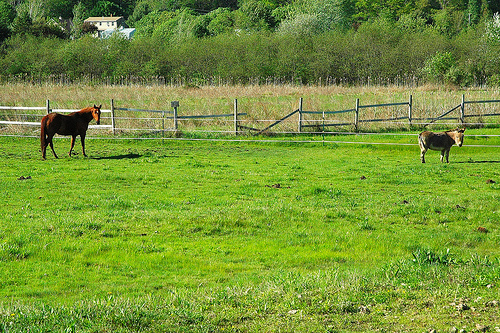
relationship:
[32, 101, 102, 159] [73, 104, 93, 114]
horse has mane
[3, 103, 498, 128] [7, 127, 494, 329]
fence by field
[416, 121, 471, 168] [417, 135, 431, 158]
donkey has tail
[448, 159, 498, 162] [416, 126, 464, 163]
shadow on donkey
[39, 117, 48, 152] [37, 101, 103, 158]
tail of horse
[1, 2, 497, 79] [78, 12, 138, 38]
trees around house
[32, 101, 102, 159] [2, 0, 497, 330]
horse in a field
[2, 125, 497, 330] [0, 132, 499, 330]
grass in green pasture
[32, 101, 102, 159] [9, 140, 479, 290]
horse in grass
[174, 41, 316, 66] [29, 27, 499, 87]
leaves on tree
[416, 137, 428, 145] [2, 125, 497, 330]
part of grass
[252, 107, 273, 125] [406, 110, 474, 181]
part of horse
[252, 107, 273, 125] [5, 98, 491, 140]
part of fence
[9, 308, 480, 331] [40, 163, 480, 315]
edge of lawn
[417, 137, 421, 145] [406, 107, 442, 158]
part of tail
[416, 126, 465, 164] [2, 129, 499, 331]
donkey in pasture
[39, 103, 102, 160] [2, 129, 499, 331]
horse in pasture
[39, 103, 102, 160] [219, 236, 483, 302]
horse in grass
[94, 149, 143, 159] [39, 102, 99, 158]
shadow of horse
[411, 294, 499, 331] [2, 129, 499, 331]
rocks in pasture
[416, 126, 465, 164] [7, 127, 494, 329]
donkey in field